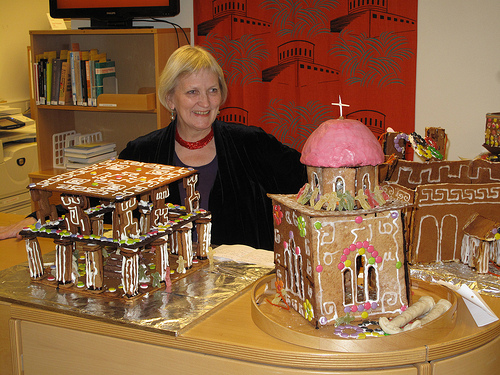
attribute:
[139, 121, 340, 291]
jacket — Black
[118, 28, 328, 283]
woman — Seated 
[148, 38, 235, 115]
hair — Blonde 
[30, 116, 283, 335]
structure — in the picture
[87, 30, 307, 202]
woman — Seated 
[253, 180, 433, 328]
bread — in the picture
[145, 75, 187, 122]
ear — Pierced